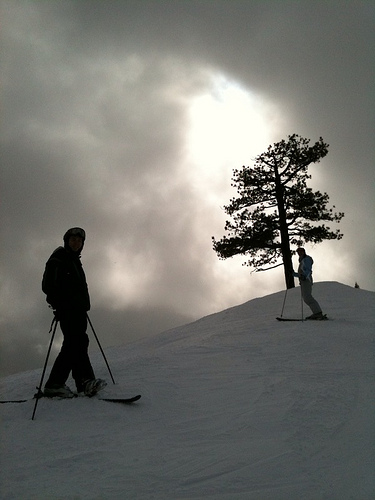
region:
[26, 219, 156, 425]
skier with skis and poles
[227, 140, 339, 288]
tree at top of skiing mountain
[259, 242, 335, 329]
a skiier on a ski mountain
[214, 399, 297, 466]
snow on a ski mountain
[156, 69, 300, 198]
the sun peeking through the clouds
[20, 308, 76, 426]
a ski pole held by a skier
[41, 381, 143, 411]
skis on the foot of a skier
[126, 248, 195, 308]
clouds above a ski mountain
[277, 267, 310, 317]
ski poles held by a skier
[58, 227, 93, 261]
the head of a skier on a ski mountain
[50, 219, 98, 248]
Person wearing helmet.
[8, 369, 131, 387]
Person holding 2 poles.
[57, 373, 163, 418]
Person has 2 skis on feet.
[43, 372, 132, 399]
Person wearing boots.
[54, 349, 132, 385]
Person wearing dark pants.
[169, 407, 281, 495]
Ground is covered in snow.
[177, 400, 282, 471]
Snow on ground is white.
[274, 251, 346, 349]
Person standing on top of hill.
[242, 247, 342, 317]
Tree on top of hill.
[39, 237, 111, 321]
Person wearing dark jacket.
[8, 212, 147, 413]
Man in black on skiis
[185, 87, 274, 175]
sun peeking through the clouds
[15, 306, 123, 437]
ski poles in man's hands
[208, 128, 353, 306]
tree on the snowy hill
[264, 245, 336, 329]
person on skiis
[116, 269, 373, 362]
hill covered in a layer of snow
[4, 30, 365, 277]
clouds in the sky covering the sun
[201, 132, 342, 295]
evergreen tree on snowy hill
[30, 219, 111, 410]
man in black ski suit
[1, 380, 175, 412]
skis on man's feet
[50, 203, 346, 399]
The people are skiing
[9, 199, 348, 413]
The people are silhouettes because of shadow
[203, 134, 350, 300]
There is a tree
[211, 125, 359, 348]
The tree is on top of the hill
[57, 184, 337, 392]
People are on top of the hill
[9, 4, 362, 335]
The sky is dark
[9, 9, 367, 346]
The sky is cloudy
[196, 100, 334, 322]
There is only one tree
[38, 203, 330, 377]
There are two skiiers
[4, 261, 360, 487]
There is snow on the hill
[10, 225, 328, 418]
two people skiing on hill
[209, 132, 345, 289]
tree on top of hill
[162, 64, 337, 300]
light showing through clouds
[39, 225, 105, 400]
man all in black snow gear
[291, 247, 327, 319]
person in blue jacket and white snowpants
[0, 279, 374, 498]
a snow covered hill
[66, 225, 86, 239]
snow goggles on head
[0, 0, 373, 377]
a grey cloudy sky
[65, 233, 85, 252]
a smiling face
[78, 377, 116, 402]
shoe lifted off of ski